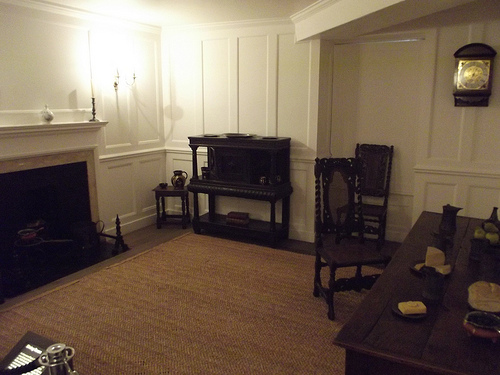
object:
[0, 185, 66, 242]
fire place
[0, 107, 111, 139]
mantle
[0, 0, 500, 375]
picture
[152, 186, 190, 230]
table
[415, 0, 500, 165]
wall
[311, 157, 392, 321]
chair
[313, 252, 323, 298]
leg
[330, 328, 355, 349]
edge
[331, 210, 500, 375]
table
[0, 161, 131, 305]
fireplace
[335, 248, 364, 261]
dark brown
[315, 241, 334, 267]
oak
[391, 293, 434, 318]
dish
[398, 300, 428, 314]
butter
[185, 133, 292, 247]
wooden hutch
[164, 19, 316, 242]
wall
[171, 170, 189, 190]
jug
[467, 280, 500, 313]
loaf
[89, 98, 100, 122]
candle holder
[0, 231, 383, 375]
carpet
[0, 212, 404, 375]
floor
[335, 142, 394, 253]
chair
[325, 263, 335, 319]
leg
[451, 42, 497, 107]
clock